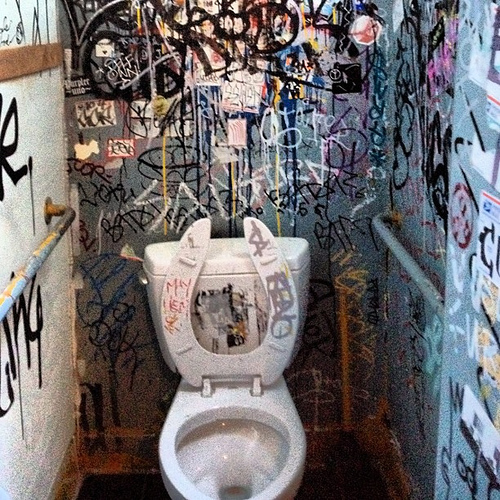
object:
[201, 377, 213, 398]
hinges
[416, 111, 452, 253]
grafitti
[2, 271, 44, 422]
grafitti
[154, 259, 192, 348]
grafitti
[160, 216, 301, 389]
lid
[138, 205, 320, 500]
toilet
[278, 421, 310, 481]
rim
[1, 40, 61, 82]
board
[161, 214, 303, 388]
seat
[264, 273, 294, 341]
graffiti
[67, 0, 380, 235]
graffiti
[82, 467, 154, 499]
floor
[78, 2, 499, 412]
wall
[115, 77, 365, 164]
wall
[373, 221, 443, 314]
hand rail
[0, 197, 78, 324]
hand rail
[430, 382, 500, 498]
drawing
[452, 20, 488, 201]
painted graffiti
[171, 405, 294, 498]
bowl area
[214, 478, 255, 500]
drain hole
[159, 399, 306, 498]
bowl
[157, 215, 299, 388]
tank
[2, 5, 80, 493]
wall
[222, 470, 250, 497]
water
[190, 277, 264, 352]
graffiti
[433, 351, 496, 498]
bart simpson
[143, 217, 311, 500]
ceramic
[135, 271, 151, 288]
flusher